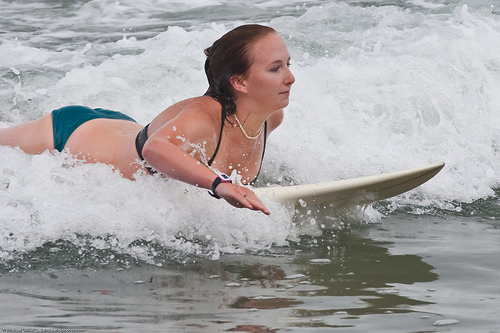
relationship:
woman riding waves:
[2, 13, 299, 218] [4, 3, 493, 256]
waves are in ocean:
[4, 3, 493, 256] [3, 4, 498, 332]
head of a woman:
[205, 28, 300, 117] [2, 13, 299, 218]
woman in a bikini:
[2, 13, 299, 218] [49, 101, 269, 191]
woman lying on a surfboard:
[2, 13, 299, 218] [240, 149, 449, 225]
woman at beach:
[2, 13, 299, 218] [3, 4, 498, 332]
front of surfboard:
[405, 153, 447, 192] [240, 149, 449, 225]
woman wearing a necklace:
[2, 13, 299, 218] [231, 102, 270, 147]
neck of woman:
[234, 96, 271, 136] [2, 13, 299, 218]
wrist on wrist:
[205, 173, 230, 198] [199, 167, 233, 197]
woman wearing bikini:
[2, 13, 299, 218] [49, 101, 269, 191]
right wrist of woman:
[199, 167, 233, 197] [2, 13, 299, 218]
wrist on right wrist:
[205, 173, 230, 198] [199, 167, 233, 197]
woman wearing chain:
[2, 13, 299, 218] [231, 102, 270, 147]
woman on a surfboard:
[2, 13, 299, 218] [240, 149, 449, 225]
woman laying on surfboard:
[2, 13, 299, 218] [240, 149, 449, 225]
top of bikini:
[134, 97, 275, 192] [49, 101, 269, 191]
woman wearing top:
[2, 13, 299, 218] [134, 97, 275, 192]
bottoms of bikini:
[41, 102, 136, 162] [49, 101, 269, 191]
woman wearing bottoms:
[2, 13, 299, 218] [41, 102, 136, 162]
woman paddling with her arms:
[2, 13, 299, 218] [148, 117, 275, 217]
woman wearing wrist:
[2, 13, 299, 218] [205, 173, 230, 198]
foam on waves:
[0, 21, 499, 262] [4, 3, 493, 256]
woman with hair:
[2, 13, 299, 218] [193, 23, 272, 112]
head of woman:
[205, 28, 300, 117] [2, 13, 299, 218]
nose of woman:
[282, 66, 299, 88] [2, 13, 299, 218]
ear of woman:
[228, 76, 247, 95] [2, 13, 299, 218]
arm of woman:
[148, 117, 275, 217] [2, 13, 299, 218]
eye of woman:
[269, 62, 285, 78] [2, 13, 299, 218]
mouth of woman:
[278, 93, 296, 96] [2, 13, 299, 218]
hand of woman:
[217, 180, 269, 213] [2, 13, 299, 218]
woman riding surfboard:
[2, 13, 299, 218] [240, 149, 449, 225]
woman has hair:
[2, 13, 299, 218] [193, 23, 272, 112]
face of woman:
[230, 35, 298, 112] [2, 13, 299, 218]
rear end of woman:
[41, 102, 136, 162] [2, 13, 299, 218]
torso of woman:
[68, 114, 160, 181] [2, 13, 299, 218]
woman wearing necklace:
[2, 13, 299, 218] [231, 102, 270, 147]